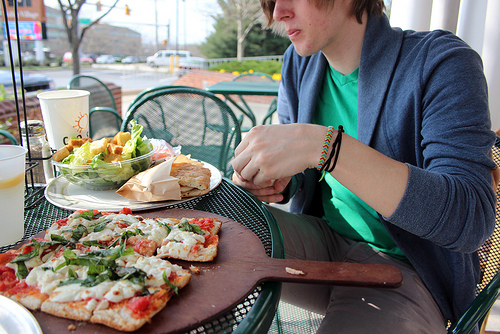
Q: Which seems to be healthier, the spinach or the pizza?
A: The spinach is healthier than the pizza.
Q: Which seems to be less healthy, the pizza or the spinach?
A: The pizza is less healthy than the spinach.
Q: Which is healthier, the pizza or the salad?
A: The salad is healthier than the pizza.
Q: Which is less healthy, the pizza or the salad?
A: The pizza is less healthy than the salad.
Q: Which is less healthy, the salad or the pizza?
A: The pizza is less healthy than the salad.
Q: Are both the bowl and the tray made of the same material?
A: No, the bowl is made of plastic and the tray is made of wood.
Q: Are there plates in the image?
A: Yes, there is a plate.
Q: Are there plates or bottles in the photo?
A: Yes, there is a plate.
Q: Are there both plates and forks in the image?
A: No, there is a plate but no forks.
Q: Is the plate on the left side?
A: Yes, the plate is on the left of the image.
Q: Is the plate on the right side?
A: No, the plate is on the left of the image.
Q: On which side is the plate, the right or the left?
A: The plate is on the left of the image.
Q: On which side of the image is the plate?
A: The plate is on the left of the image.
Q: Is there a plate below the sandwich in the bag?
A: Yes, there is a plate below the sandwich.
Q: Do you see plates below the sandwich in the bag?
A: Yes, there is a plate below the sandwich.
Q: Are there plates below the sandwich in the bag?
A: Yes, there is a plate below the sandwich.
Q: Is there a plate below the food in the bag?
A: Yes, there is a plate below the sandwich.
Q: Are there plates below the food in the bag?
A: Yes, there is a plate below the sandwich.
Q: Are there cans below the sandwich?
A: No, there is a plate below the sandwich.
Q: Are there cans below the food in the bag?
A: No, there is a plate below the sandwich.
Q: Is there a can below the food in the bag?
A: No, there is a plate below the sandwich.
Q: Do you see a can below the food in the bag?
A: No, there is a plate below the sandwich.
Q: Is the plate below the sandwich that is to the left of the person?
A: Yes, the plate is below the sandwich.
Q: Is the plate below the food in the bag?
A: Yes, the plate is below the sandwich.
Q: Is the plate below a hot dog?
A: No, the plate is below the sandwich.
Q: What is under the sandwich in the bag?
A: The plate is under the sandwich.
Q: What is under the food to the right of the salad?
A: The plate is under the sandwich.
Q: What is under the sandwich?
A: The plate is under the sandwich.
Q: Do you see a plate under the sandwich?
A: Yes, there is a plate under the sandwich.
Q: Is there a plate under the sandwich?
A: Yes, there is a plate under the sandwich.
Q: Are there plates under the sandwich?
A: Yes, there is a plate under the sandwich.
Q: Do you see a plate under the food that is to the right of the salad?
A: Yes, there is a plate under the sandwich.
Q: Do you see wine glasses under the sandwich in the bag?
A: No, there is a plate under the sandwich.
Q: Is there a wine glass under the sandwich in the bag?
A: No, there is a plate under the sandwich.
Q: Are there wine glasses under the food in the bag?
A: No, there is a plate under the sandwich.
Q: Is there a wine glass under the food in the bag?
A: No, there is a plate under the sandwich.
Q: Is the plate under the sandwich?
A: Yes, the plate is under the sandwich.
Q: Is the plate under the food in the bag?
A: Yes, the plate is under the sandwich.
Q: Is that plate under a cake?
A: No, the plate is under the sandwich.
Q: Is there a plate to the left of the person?
A: Yes, there is a plate to the left of the person.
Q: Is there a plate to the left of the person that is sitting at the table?
A: Yes, there is a plate to the left of the person.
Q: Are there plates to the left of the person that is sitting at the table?
A: Yes, there is a plate to the left of the person.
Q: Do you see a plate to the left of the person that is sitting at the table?
A: Yes, there is a plate to the left of the person.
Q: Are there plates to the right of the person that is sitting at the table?
A: No, the plate is to the left of the person.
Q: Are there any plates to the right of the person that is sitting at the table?
A: No, the plate is to the left of the person.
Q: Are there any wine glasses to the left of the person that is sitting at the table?
A: No, there is a plate to the left of the person.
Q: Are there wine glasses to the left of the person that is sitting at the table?
A: No, there is a plate to the left of the person.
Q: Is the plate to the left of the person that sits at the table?
A: Yes, the plate is to the left of the person.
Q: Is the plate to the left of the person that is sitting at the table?
A: Yes, the plate is to the left of the person.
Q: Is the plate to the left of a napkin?
A: No, the plate is to the left of the person.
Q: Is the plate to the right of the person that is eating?
A: No, the plate is to the left of the person.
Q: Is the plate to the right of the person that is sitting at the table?
A: No, the plate is to the left of the person.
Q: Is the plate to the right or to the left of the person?
A: The plate is to the left of the person.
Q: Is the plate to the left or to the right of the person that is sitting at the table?
A: The plate is to the left of the person.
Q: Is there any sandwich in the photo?
A: Yes, there is a sandwich.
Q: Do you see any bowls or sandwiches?
A: Yes, there is a sandwich.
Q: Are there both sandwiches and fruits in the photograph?
A: No, there is a sandwich but no fruits.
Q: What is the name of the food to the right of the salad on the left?
A: The food is a sandwich.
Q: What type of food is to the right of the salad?
A: The food is a sandwich.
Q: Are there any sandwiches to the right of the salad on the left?
A: Yes, there is a sandwich to the right of the salad.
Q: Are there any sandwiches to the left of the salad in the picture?
A: No, the sandwich is to the right of the salad.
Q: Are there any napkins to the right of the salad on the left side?
A: No, there is a sandwich to the right of the salad.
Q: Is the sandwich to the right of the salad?
A: Yes, the sandwich is to the right of the salad.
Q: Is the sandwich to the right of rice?
A: No, the sandwich is to the right of the salad.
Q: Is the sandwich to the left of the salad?
A: No, the sandwich is to the right of the salad.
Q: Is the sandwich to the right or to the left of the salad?
A: The sandwich is to the right of the salad.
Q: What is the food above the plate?
A: The food is a sandwich.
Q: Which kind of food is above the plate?
A: The food is a sandwich.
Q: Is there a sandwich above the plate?
A: Yes, there is a sandwich above the plate.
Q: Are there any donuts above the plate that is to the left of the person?
A: No, there is a sandwich above the plate.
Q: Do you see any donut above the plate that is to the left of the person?
A: No, there is a sandwich above the plate.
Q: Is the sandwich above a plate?
A: Yes, the sandwich is above a plate.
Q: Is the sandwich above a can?
A: No, the sandwich is above a plate.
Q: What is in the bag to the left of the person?
A: The sandwich is in the bag.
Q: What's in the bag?
A: The sandwich is in the bag.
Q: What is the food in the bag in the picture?
A: The food is a sandwich.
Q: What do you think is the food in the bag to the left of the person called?
A: The food is a sandwich.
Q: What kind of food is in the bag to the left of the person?
A: The food is a sandwich.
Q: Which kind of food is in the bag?
A: The food is a sandwich.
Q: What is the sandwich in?
A: The sandwich is in the bag.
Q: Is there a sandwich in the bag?
A: Yes, there is a sandwich in the bag.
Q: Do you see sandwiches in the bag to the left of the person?
A: Yes, there is a sandwich in the bag.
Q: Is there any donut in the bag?
A: No, there is a sandwich in the bag.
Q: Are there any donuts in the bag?
A: No, there is a sandwich in the bag.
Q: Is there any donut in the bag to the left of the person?
A: No, there is a sandwich in the bag.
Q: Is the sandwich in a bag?
A: Yes, the sandwich is in a bag.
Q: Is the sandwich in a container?
A: No, the sandwich is in a bag.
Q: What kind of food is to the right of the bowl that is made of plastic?
A: The food is a sandwich.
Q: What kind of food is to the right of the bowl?
A: The food is a sandwich.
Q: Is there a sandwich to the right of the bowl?
A: Yes, there is a sandwich to the right of the bowl.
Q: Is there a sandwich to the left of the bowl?
A: No, the sandwich is to the right of the bowl.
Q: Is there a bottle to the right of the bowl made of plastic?
A: No, there is a sandwich to the right of the bowl.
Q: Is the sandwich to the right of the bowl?
A: Yes, the sandwich is to the right of the bowl.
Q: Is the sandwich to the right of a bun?
A: No, the sandwich is to the right of the bowl.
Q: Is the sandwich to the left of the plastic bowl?
A: No, the sandwich is to the right of the bowl.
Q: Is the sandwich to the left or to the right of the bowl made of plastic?
A: The sandwich is to the right of the bowl.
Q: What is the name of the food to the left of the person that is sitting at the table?
A: The food is a sandwich.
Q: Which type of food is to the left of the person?
A: The food is a sandwich.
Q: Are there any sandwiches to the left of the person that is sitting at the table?
A: Yes, there is a sandwich to the left of the person.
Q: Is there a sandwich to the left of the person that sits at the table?
A: Yes, there is a sandwich to the left of the person.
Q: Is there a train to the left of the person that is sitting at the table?
A: No, there is a sandwich to the left of the person.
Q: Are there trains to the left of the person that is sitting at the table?
A: No, there is a sandwich to the left of the person.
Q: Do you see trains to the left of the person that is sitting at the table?
A: No, there is a sandwich to the left of the person.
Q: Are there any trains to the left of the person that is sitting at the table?
A: No, there is a sandwich to the left of the person.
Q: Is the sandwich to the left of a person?
A: Yes, the sandwich is to the left of a person.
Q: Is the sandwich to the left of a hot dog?
A: No, the sandwich is to the left of a person.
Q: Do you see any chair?
A: Yes, there is a chair.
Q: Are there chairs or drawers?
A: Yes, there is a chair.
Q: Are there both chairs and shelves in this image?
A: No, there is a chair but no shelves.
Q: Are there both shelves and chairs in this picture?
A: No, there is a chair but no shelves.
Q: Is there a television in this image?
A: No, there are no televisions.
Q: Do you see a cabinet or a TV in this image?
A: No, there are no televisions or cabinets.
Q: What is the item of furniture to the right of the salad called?
A: The piece of furniture is a chair.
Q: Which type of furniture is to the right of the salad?
A: The piece of furniture is a chair.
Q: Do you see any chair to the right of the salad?
A: Yes, there is a chair to the right of the salad.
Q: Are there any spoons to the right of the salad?
A: No, there is a chair to the right of the salad.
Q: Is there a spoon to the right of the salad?
A: No, there is a chair to the right of the salad.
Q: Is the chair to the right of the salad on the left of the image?
A: Yes, the chair is to the right of the salad.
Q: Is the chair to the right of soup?
A: No, the chair is to the right of the salad.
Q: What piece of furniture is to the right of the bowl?
A: The piece of furniture is a chair.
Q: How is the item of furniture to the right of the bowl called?
A: The piece of furniture is a chair.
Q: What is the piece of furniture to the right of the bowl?
A: The piece of furniture is a chair.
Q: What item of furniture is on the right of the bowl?
A: The piece of furniture is a chair.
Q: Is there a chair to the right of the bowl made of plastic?
A: Yes, there is a chair to the right of the bowl.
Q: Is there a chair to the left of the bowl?
A: No, the chair is to the right of the bowl.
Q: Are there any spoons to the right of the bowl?
A: No, there is a chair to the right of the bowl.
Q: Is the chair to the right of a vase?
A: No, the chair is to the right of a bowl.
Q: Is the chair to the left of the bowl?
A: No, the chair is to the right of the bowl.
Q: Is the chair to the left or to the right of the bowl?
A: The chair is to the right of the bowl.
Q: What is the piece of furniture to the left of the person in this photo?
A: The piece of furniture is a chair.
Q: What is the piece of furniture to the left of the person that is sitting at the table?
A: The piece of furniture is a chair.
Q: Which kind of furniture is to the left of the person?
A: The piece of furniture is a chair.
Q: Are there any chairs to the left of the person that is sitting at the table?
A: Yes, there is a chair to the left of the person.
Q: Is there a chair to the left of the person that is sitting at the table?
A: Yes, there is a chair to the left of the person.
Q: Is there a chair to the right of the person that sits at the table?
A: No, the chair is to the left of the person.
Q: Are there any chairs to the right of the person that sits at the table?
A: No, the chair is to the left of the person.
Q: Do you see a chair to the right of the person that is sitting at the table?
A: No, the chair is to the left of the person.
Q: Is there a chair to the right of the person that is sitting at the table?
A: No, the chair is to the left of the person.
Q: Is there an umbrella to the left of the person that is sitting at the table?
A: No, there is a chair to the left of the person.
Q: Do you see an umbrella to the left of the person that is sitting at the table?
A: No, there is a chair to the left of the person.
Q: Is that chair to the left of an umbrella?
A: No, the chair is to the left of a person.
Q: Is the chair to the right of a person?
A: No, the chair is to the left of a person.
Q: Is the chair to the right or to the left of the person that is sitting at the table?
A: The chair is to the left of the person.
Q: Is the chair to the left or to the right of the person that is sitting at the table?
A: The chair is to the left of the person.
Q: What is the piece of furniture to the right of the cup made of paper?
A: The piece of furniture is a chair.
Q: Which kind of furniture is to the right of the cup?
A: The piece of furniture is a chair.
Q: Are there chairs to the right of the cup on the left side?
A: Yes, there is a chair to the right of the cup.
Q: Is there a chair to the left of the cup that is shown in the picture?
A: No, the chair is to the right of the cup.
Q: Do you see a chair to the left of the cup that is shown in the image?
A: No, the chair is to the right of the cup.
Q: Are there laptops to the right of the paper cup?
A: No, there is a chair to the right of the cup.